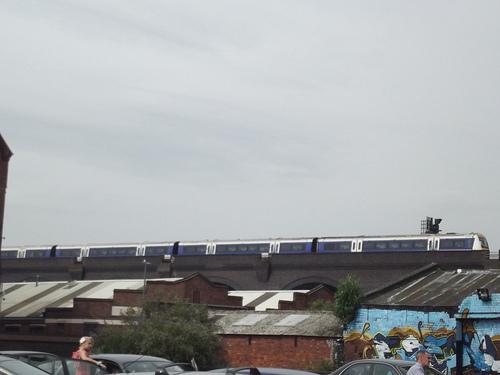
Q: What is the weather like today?
A: It is cloudy.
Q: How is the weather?
A: It is cloudy.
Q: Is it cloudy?
A: Yes, it is cloudy.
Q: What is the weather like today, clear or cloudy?
A: It is cloudy.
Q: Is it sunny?
A: No, it is cloudy.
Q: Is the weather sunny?
A: No, it is cloudy.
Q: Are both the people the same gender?
A: No, they are both male and female.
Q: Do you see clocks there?
A: No, there are no clocks.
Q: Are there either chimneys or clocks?
A: No, there are no clocks or chimneys.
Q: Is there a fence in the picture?
A: No, there are no fences.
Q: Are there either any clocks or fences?
A: No, there are no fences or clocks.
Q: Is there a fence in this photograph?
A: No, there are no fences.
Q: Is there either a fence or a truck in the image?
A: No, there are no fences or trucks.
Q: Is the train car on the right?
A: Yes, the train car is on the right of the image.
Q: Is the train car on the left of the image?
A: No, the train car is on the right of the image.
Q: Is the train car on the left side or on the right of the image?
A: The train car is on the right of the image.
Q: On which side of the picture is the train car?
A: The train car is on the right of the image.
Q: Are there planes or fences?
A: No, there are no fences or planes.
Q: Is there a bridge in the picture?
A: Yes, there is a bridge.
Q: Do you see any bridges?
A: Yes, there is a bridge.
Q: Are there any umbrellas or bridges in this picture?
A: Yes, there is a bridge.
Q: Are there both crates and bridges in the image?
A: No, there is a bridge but no crates.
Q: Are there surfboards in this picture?
A: No, there are no surfboards.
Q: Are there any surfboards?
A: No, there are no surfboards.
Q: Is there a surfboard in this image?
A: No, there are no surfboards.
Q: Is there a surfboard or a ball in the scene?
A: No, there are no surfboards or balls.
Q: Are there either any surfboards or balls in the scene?
A: No, there are no surfboards or balls.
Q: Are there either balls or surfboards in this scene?
A: No, there are no surfboards or balls.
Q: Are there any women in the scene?
A: Yes, there is a woman.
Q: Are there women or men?
A: Yes, there is a woman.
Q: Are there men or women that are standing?
A: Yes, the woman is standing.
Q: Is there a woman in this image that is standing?
A: Yes, there is a woman that is standing.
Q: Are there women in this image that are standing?
A: Yes, there is a woman that is standing.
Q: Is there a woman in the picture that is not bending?
A: Yes, there is a woman that is standing.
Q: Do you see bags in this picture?
A: No, there are no bags.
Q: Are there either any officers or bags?
A: No, there are no bags or officers.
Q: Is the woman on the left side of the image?
A: Yes, the woman is on the left of the image.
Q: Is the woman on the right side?
A: No, the woman is on the left of the image.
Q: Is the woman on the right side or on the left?
A: The woman is on the left of the image.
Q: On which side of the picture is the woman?
A: The woman is on the left of the image.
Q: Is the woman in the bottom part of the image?
A: Yes, the woman is in the bottom of the image.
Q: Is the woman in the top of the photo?
A: No, the woman is in the bottom of the image.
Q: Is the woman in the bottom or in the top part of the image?
A: The woman is in the bottom of the image.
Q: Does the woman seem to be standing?
A: Yes, the woman is standing.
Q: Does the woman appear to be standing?
A: Yes, the woman is standing.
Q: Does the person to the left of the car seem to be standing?
A: Yes, the woman is standing.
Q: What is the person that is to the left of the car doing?
A: The woman is standing.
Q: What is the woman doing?
A: The woman is standing.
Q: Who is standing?
A: The woman is standing.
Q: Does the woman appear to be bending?
A: No, the woman is standing.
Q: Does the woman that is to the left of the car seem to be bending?
A: No, the woman is standing.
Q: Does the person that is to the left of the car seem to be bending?
A: No, the woman is standing.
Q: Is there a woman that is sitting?
A: No, there is a woman but she is standing.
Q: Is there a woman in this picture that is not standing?
A: No, there is a woman but she is standing.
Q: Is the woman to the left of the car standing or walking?
A: The woman is standing.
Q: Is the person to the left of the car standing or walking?
A: The woman is standing.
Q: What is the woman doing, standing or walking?
A: The woman is standing.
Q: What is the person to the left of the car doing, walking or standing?
A: The woman is standing.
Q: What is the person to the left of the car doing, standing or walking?
A: The woman is standing.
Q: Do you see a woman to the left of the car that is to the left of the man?
A: Yes, there is a woman to the left of the car.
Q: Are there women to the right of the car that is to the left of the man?
A: No, the woman is to the left of the car.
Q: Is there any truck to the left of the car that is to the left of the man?
A: No, there is a woman to the left of the car.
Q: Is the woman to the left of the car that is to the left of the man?
A: Yes, the woman is to the left of the car.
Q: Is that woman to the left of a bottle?
A: No, the woman is to the left of the car.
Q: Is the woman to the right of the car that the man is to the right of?
A: No, the woman is to the left of the car.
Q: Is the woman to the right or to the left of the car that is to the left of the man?
A: The woman is to the left of the car.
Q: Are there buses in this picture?
A: No, there are no buses.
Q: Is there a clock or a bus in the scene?
A: No, there are no buses or clocks.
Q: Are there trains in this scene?
A: Yes, there is a train.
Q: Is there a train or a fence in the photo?
A: Yes, there is a train.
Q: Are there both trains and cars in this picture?
A: Yes, there are both a train and a car.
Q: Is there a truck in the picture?
A: No, there are no trucks.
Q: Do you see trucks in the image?
A: No, there are no trucks.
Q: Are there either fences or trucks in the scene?
A: No, there are no trucks or fences.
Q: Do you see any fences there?
A: No, there are no fences.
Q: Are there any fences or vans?
A: No, there are no fences or vans.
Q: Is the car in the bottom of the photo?
A: Yes, the car is in the bottom of the image.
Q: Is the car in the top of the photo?
A: No, the car is in the bottom of the image.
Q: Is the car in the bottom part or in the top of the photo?
A: The car is in the bottom of the image.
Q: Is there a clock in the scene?
A: No, there are no clocks.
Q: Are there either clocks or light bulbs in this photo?
A: No, there are no clocks or light bulbs.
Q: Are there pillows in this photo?
A: No, there are no pillows.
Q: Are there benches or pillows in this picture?
A: No, there are no pillows or benches.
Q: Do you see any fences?
A: No, there are no fences.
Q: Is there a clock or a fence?
A: No, there are no fences or clocks.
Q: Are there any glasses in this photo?
A: No, there are no glasses.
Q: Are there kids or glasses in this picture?
A: No, there are no glasses or kids.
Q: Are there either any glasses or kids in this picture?
A: No, there are no glasses or kids.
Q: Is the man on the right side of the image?
A: Yes, the man is on the right of the image.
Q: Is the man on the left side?
A: No, the man is on the right of the image.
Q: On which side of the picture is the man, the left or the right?
A: The man is on the right of the image.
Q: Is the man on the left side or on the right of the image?
A: The man is on the right of the image.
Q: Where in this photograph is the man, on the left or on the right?
A: The man is on the right of the image.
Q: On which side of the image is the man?
A: The man is on the right of the image.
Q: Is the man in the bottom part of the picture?
A: Yes, the man is in the bottom of the image.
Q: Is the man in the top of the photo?
A: No, the man is in the bottom of the image.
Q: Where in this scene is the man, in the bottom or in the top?
A: The man is in the bottom of the image.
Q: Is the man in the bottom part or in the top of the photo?
A: The man is in the bottom of the image.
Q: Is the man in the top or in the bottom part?
A: The man is in the bottom of the image.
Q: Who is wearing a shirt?
A: The man is wearing a shirt.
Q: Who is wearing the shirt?
A: The man is wearing a shirt.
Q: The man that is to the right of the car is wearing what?
A: The man is wearing a shirt.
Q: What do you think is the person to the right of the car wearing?
A: The man is wearing a shirt.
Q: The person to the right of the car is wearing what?
A: The man is wearing a shirt.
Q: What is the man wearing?
A: The man is wearing a shirt.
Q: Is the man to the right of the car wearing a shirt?
A: Yes, the man is wearing a shirt.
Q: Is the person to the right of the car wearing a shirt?
A: Yes, the man is wearing a shirt.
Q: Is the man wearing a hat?
A: No, the man is wearing a shirt.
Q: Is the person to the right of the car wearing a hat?
A: No, the man is wearing a shirt.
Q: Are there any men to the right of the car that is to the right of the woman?
A: Yes, there is a man to the right of the car.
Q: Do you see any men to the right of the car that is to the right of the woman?
A: Yes, there is a man to the right of the car.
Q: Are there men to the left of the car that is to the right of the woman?
A: No, the man is to the right of the car.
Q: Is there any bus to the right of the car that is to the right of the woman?
A: No, there is a man to the right of the car.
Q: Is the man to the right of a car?
A: Yes, the man is to the right of a car.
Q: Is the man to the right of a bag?
A: No, the man is to the right of a car.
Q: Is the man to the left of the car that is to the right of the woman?
A: No, the man is to the right of the car.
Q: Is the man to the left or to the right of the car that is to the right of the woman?
A: The man is to the right of the car.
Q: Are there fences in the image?
A: No, there are no fences.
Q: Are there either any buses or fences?
A: No, there are no fences or buses.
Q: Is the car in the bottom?
A: Yes, the car is in the bottom of the image.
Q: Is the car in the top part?
A: No, the car is in the bottom of the image.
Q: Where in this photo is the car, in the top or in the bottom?
A: The car is in the bottom of the image.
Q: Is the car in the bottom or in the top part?
A: The car is in the bottom of the image.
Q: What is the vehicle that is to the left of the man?
A: The vehicle is a car.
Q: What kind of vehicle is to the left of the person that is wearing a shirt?
A: The vehicle is a car.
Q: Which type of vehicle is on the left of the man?
A: The vehicle is a car.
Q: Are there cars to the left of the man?
A: Yes, there is a car to the left of the man.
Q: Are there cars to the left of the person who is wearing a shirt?
A: Yes, there is a car to the left of the man.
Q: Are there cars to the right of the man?
A: No, the car is to the left of the man.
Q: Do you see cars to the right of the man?
A: No, the car is to the left of the man.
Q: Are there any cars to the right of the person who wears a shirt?
A: No, the car is to the left of the man.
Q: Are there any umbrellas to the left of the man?
A: No, there is a car to the left of the man.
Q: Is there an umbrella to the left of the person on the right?
A: No, there is a car to the left of the man.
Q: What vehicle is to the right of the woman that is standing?
A: The vehicle is a car.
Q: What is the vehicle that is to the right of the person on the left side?
A: The vehicle is a car.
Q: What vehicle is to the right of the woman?
A: The vehicle is a car.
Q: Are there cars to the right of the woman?
A: Yes, there is a car to the right of the woman.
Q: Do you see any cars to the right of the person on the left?
A: Yes, there is a car to the right of the woman.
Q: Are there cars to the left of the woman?
A: No, the car is to the right of the woman.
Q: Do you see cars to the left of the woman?
A: No, the car is to the right of the woman.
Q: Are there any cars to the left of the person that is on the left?
A: No, the car is to the right of the woman.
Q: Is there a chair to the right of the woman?
A: No, there is a car to the right of the woman.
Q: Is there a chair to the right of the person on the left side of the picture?
A: No, there is a car to the right of the woman.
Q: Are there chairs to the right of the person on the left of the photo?
A: No, there is a car to the right of the woman.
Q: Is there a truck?
A: No, there are no trucks.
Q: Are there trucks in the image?
A: No, there are no trucks.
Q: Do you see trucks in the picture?
A: No, there are no trucks.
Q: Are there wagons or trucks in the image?
A: No, there are no trucks or wagons.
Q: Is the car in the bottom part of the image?
A: Yes, the car is in the bottom of the image.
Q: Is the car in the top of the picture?
A: No, the car is in the bottom of the image.